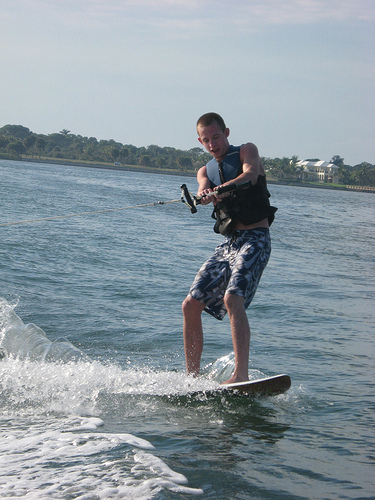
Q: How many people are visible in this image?
A: One.